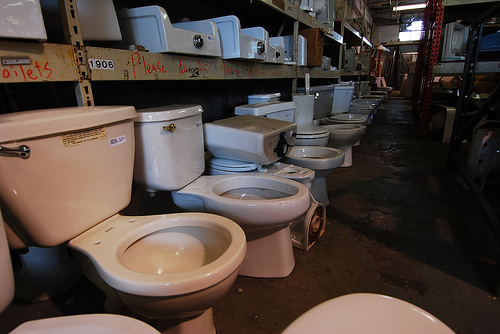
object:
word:
[131, 52, 165, 78]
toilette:
[0, 100, 250, 332]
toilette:
[131, 99, 311, 275]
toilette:
[235, 103, 330, 147]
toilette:
[316, 119, 370, 169]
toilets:
[0, 77, 408, 328]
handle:
[0, 145, 33, 159]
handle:
[164, 123, 176, 132]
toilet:
[235, 97, 346, 208]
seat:
[69, 210, 245, 296]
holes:
[94, 243, 99, 245]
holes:
[128, 220, 133, 222]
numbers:
[89, 60, 115, 68]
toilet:
[345, 102, 372, 114]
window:
[391, 5, 426, 40]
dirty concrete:
[223, 93, 496, 330]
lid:
[132, 104, 205, 122]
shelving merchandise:
[70, 3, 299, 63]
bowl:
[117, 222, 225, 273]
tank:
[0, 97, 133, 246]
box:
[300, 23, 326, 69]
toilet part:
[122, 3, 222, 57]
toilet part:
[218, 9, 263, 57]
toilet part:
[3, 1, 49, 40]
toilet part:
[266, 33, 287, 61]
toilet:
[132, 104, 308, 278]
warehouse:
[3, 2, 496, 332]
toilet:
[210, 154, 315, 194]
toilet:
[351, 94, 382, 105]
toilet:
[0, 106, 247, 331]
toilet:
[235, 102, 329, 146]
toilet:
[292, 92, 366, 168]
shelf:
[0, 0, 371, 105]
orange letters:
[131, 52, 165, 79]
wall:
[362, 0, 500, 97]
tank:
[203, 112, 296, 163]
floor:
[219, 79, 496, 334]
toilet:
[330, 84, 365, 137]